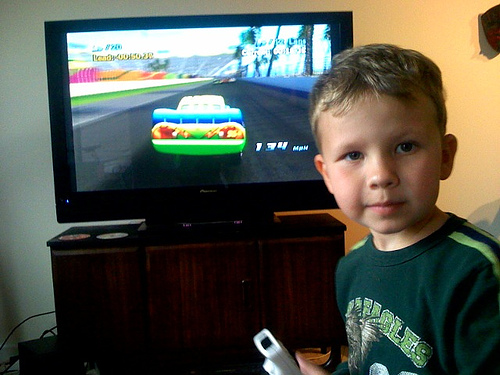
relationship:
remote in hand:
[248, 325, 299, 374] [294, 345, 342, 373]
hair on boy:
[325, 49, 405, 106] [297, 39, 472, 279]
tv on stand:
[41, 9, 369, 236] [44, 211, 348, 368]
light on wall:
[470, 7, 495, 52] [13, 4, 495, 251]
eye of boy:
[334, 148, 369, 165] [242, 33, 497, 370]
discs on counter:
[52, 219, 131, 249] [45, 216, 351, 371]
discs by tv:
[52, 219, 131, 249] [49, 37, 290, 221]